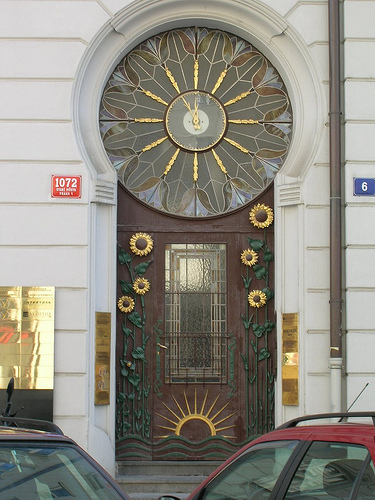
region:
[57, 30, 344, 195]
A clock on a building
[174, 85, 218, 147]
the hands of a clock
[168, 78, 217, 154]
The gold hand of a clock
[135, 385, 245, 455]
A gold sun design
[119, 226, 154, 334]
three yellow flowers on a door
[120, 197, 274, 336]
six yellow flowers on a door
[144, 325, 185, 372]
the handle on a door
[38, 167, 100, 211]
white numbers on a red sign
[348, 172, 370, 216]
a white number on a blue sign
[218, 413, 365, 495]
the top of a red car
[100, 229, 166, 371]
daisies on the door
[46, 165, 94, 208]
1072 red sign on building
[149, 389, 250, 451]
sun decoration on bottom of door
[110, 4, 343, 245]
clock above the door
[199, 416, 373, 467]
red car in front of door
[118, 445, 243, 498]
steps to the door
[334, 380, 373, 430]
car antenna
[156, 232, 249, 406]
decorative glass in the door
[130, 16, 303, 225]
stained glass flowers on the clock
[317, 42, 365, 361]
brown pipe on building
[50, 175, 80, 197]
red sign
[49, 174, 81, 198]
red sign with a white print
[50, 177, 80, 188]
1072 printed in white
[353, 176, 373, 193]
blue number sign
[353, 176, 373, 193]
6 printed on a blue sign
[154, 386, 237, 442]
yellow sun design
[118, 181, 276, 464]
brown door with a floral and sun design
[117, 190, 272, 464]
brown door with a green and yellow design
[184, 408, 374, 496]
parked red car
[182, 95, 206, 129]
golden clock hands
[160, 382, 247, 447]
a sun on a door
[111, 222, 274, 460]
a decorated brown wood door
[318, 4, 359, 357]
a long brown drain pipe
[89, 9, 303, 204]
a large round window above a door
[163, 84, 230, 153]
a clock in a window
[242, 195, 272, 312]
sunflowers decorating a door frame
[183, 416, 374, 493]
a red car in front of a building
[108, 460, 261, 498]
stone steps going up to a building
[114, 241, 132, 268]
a green leaf on a door frame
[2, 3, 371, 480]
a beautiful white building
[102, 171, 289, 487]
large tall wooden door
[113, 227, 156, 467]
decorative sunflower carving on wooden door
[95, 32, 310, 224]
large round stained glass window containing clock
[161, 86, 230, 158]
glass and metal clock within stained glass window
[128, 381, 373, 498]
red car parked in front of house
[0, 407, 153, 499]
dark blue car parked outside house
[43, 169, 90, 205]
rectangular red sign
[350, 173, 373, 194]
small blue sign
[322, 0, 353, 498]
tall thick pipe attached to building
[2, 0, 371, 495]
front of large white building